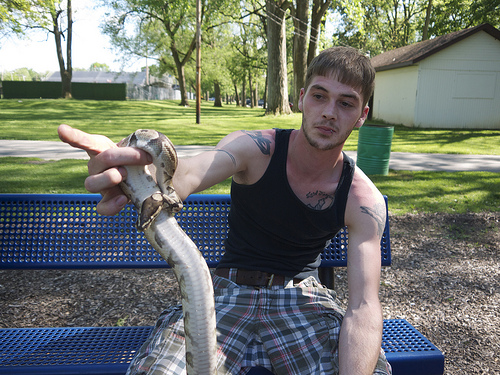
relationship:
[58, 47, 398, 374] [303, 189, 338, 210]
man has tatoo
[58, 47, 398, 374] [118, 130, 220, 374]
man has snake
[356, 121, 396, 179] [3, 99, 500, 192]
can on top of grass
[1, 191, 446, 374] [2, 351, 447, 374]
bench has edge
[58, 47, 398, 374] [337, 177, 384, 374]
man has left arm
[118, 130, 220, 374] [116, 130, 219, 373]
snake has body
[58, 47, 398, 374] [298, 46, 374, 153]
man has face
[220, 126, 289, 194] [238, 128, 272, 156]
shoulder has tattoo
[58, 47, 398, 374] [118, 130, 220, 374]
man holding snake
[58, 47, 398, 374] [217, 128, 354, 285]
man wearing tank top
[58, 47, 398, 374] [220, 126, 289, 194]
man has right shoulder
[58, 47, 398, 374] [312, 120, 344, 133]
man has mustache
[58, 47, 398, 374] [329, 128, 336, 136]
man has toothpick